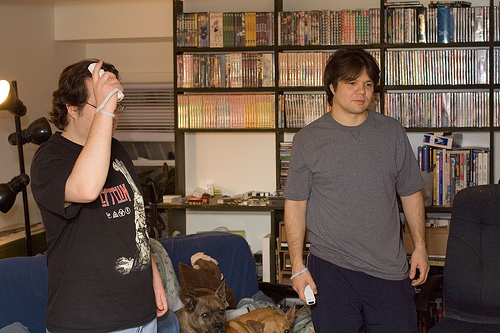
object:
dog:
[168, 279, 235, 333]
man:
[28, 58, 170, 332]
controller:
[85, 62, 126, 104]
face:
[78, 75, 125, 135]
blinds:
[115, 80, 180, 132]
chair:
[428, 183, 500, 333]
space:
[174, 85, 279, 94]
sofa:
[0, 227, 273, 330]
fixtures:
[0, 76, 53, 261]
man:
[283, 41, 430, 333]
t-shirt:
[285, 110, 433, 282]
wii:
[85, 61, 130, 107]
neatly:
[176, 94, 190, 132]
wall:
[0, 0, 82, 239]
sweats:
[307, 251, 424, 333]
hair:
[44, 56, 114, 131]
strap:
[288, 267, 312, 281]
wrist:
[288, 257, 309, 271]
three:
[0, 75, 54, 216]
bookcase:
[173, 2, 500, 274]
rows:
[205, 9, 210, 49]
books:
[209, 12, 223, 48]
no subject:
[446, 49, 455, 84]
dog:
[223, 299, 302, 333]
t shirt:
[27, 130, 158, 333]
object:
[181, 13, 184, 45]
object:
[206, 182, 216, 198]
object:
[421, 132, 455, 149]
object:
[416, 8, 425, 43]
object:
[326, 11, 330, 45]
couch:
[424, 177, 500, 333]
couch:
[1, 227, 296, 331]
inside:
[126, 14, 438, 329]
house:
[0, 0, 500, 333]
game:
[81, 62, 125, 108]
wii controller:
[299, 281, 320, 308]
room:
[0, 0, 500, 333]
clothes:
[177, 252, 239, 309]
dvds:
[173, 52, 182, 90]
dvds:
[193, 12, 199, 47]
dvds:
[241, 92, 244, 129]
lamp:
[0, 75, 31, 117]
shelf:
[177, 126, 276, 134]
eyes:
[200, 312, 211, 320]